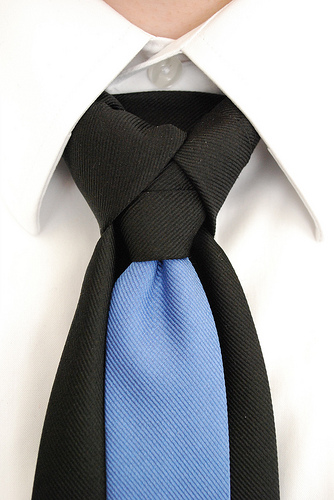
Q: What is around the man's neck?
A: A tie.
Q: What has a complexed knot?
A: The tie.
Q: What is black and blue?
A: The tie.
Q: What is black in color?
A: The knot.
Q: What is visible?
A: A tie.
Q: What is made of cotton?
A: The tie.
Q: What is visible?
A: A tie.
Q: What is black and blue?
A: A tie.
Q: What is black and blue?
A: A tie.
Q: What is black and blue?
A: A tie.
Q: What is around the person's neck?
A: Tie.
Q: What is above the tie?
A: A button.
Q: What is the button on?
A: A shirt.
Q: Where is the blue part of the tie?
A: In front of the black.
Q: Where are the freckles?
A: On the person's neck.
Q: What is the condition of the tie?
A: It is tied.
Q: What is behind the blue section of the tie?
A: The black section of the tie.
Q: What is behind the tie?
A: A white dress shirt.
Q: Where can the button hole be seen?
A: Right of the button.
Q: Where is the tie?
A: On the man.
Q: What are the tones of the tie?
A: Blue and black.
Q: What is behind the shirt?
A: A white shirt.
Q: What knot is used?
A: A standard knot.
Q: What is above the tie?
A: The neck.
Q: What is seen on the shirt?
A: A white collar.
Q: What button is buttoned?
A: The top button.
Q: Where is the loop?
A: On the neck tie.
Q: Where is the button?
A: On the neck.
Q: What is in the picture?
A: A shirt and tie.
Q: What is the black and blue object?
A: Tie.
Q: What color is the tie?
A: Black and blue.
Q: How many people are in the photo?
A: One.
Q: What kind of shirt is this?
A: Collared shirt.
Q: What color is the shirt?
A: White.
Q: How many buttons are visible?
A: One.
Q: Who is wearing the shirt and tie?
A: Man.